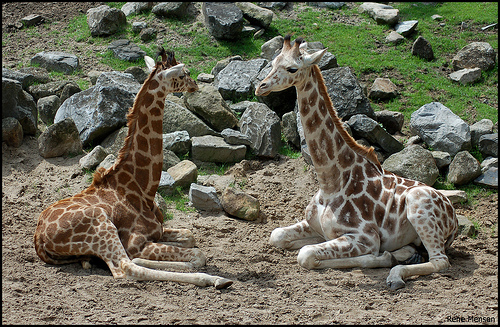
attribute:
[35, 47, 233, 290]
giraffe — laying down, sitting, mammal, comfortable, yellow, brown, sitting down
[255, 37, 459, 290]
giraffe — laying down, white, brown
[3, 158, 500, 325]
ground — sandy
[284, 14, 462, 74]
grass — green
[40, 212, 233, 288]
leg — long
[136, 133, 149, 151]
spot — dark brown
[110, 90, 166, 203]
neck — long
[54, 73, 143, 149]
rock — large